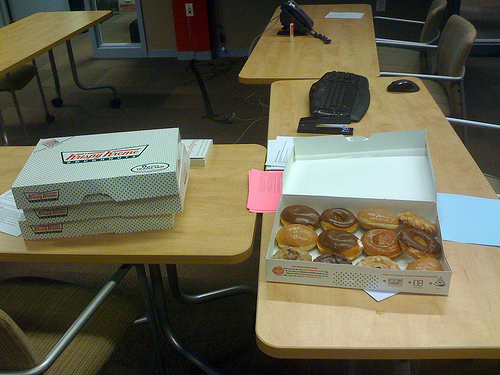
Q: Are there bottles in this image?
A: No, there are no bottles.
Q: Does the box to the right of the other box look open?
A: Yes, the box is open.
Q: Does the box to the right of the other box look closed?
A: No, the box is open.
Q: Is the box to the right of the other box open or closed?
A: The box is open.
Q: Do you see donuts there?
A: Yes, there is a donut.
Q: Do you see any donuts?
A: Yes, there is a donut.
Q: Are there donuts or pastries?
A: Yes, there is a donut.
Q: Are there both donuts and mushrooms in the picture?
A: No, there is a donut but no mushrooms.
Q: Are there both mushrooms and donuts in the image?
A: No, there is a donut but no mushrooms.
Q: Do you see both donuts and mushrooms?
A: No, there is a donut but no mushrooms.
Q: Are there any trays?
A: No, there are no trays.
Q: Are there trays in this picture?
A: No, there are no trays.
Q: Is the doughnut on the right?
A: Yes, the doughnut is on the right of the image.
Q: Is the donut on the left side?
A: No, the donut is on the right of the image.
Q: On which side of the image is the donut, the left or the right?
A: The donut is on the right of the image.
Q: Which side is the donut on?
A: The donut is on the right of the image.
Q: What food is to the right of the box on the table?
A: The food is a donut.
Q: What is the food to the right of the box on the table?
A: The food is a donut.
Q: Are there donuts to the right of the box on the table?
A: Yes, there is a donut to the right of the box.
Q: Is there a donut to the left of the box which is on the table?
A: No, the donut is to the right of the box.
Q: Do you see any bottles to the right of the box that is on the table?
A: No, there is a donut to the right of the box.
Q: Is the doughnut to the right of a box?
A: Yes, the doughnut is to the right of a box.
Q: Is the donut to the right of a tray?
A: No, the donut is to the right of a box.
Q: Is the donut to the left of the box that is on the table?
A: No, the donut is to the right of the box.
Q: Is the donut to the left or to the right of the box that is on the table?
A: The donut is to the right of the box.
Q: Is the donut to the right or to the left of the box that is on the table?
A: The donut is to the right of the box.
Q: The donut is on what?
A: The donut is on the table.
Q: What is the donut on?
A: The donut is on the table.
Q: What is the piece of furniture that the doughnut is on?
A: The piece of furniture is a table.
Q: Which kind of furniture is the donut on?
A: The doughnut is on the table.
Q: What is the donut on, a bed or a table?
A: The donut is on a table.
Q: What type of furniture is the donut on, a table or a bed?
A: The donut is on a table.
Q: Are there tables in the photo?
A: Yes, there is a table.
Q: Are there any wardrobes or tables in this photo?
A: Yes, there is a table.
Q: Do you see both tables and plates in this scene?
A: No, there is a table but no plates.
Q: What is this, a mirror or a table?
A: This is a table.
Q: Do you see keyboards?
A: Yes, there is a keyboard.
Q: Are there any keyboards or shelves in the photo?
A: Yes, there is a keyboard.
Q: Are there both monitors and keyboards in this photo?
A: No, there is a keyboard but no monitors.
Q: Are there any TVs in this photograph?
A: No, there are no tvs.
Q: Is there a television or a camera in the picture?
A: No, there are no televisions or cameras.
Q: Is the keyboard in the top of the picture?
A: Yes, the keyboard is in the top of the image.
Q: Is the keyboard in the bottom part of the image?
A: No, the keyboard is in the top of the image.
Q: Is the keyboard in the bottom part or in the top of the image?
A: The keyboard is in the top of the image.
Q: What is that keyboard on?
A: The keyboard is on the table.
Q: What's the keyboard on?
A: The keyboard is on the table.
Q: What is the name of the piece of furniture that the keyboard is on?
A: The piece of furniture is a table.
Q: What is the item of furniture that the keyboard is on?
A: The piece of furniture is a table.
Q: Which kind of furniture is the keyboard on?
A: The keyboard is on the table.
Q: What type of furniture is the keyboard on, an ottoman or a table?
A: The keyboard is on a table.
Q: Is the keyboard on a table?
A: Yes, the keyboard is on a table.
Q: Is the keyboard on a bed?
A: No, the keyboard is on a table.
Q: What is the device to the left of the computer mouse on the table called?
A: The device is a keyboard.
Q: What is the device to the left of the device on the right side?
A: The device is a keyboard.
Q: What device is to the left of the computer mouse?
A: The device is a keyboard.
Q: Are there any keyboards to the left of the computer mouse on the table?
A: Yes, there is a keyboard to the left of the computer mouse.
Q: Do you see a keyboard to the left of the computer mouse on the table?
A: Yes, there is a keyboard to the left of the computer mouse.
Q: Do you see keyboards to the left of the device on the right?
A: Yes, there is a keyboard to the left of the computer mouse.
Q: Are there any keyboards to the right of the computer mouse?
A: No, the keyboard is to the left of the computer mouse.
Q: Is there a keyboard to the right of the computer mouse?
A: No, the keyboard is to the left of the computer mouse.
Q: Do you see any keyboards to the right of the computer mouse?
A: No, the keyboard is to the left of the computer mouse.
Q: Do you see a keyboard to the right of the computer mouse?
A: No, the keyboard is to the left of the computer mouse.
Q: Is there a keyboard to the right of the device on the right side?
A: No, the keyboard is to the left of the computer mouse.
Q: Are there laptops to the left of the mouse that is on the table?
A: No, there is a keyboard to the left of the mouse.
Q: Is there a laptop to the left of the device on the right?
A: No, there is a keyboard to the left of the mouse.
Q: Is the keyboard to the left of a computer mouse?
A: Yes, the keyboard is to the left of a computer mouse.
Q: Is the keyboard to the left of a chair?
A: No, the keyboard is to the left of a computer mouse.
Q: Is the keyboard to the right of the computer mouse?
A: No, the keyboard is to the left of the computer mouse.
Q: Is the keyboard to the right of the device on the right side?
A: No, the keyboard is to the left of the computer mouse.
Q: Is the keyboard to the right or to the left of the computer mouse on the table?
A: The keyboard is to the left of the mouse.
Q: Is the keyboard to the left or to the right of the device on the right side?
A: The keyboard is to the left of the mouse.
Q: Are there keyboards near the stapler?
A: Yes, there is a keyboard near the stapler.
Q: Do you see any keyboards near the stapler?
A: Yes, there is a keyboard near the stapler.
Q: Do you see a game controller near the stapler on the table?
A: No, there is a keyboard near the stapler.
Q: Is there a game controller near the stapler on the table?
A: No, there is a keyboard near the stapler.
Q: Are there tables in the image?
A: Yes, there is a table.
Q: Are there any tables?
A: Yes, there is a table.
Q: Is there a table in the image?
A: Yes, there is a table.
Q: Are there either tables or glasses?
A: Yes, there is a table.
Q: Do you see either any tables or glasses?
A: Yes, there is a table.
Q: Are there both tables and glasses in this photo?
A: No, there is a table but no glasses.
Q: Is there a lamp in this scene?
A: No, there are no lamps.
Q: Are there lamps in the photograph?
A: No, there are no lamps.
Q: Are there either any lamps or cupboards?
A: No, there are no lamps or cupboards.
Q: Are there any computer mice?
A: Yes, there is a computer mouse.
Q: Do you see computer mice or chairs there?
A: Yes, there is a computer mouse.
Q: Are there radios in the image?
A: No, there are no radios.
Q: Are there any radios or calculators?
A: No, there are no radios or calculators.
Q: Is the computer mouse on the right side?
A: Yes, the computer mouse is on the right of the image.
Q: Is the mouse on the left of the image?
A: No, the mouse is on the right of the image.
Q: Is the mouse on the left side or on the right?
A: The mouse is on the right of the image.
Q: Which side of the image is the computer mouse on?
A: The computer mouse is on the right of the image.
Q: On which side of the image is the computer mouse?
A: The computer mouse is on the right of the image.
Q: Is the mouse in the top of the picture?
A: Yes, the mouse is in the top of the image.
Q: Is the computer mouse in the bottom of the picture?
A: No, the computer mouse is in the top of the image.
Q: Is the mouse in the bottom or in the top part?
A: The mouse is in the top of the image.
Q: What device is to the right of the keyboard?
A: The device is a computer mouse.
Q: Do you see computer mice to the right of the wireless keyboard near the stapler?
A: Yes, there is a computer mouse to the right of the keyboard.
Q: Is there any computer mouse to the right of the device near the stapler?
A: Yes, there is a computer mouse to the right of the keyboard.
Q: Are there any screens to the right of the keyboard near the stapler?
A: No, there is a computer mouse to the right of the keyboard.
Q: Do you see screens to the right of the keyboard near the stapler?
A: No, there is a computer mouse to the right of the keyboard.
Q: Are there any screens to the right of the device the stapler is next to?
A: No, there is a computer mouse to the right of the keyboard.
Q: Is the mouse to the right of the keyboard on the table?
A: Yes, the mouse is to the right of the keyboard.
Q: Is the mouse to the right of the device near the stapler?
A: Yes, the mouse is to the right of the keyboard.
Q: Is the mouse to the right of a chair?
A: No, the mouse is to the right of the keyboard.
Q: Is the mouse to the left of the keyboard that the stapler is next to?
A: No, the mouse is to the right of the keyboard.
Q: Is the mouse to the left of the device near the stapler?
A: No, the mouse is to the right of the keyboard.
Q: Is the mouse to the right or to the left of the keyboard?
A: The mouse is to the right of the keyboard.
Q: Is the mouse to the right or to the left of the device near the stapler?
A: The mouse is to the right of the keyboard.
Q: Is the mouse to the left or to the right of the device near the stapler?
A: The mouse is to the right of the keyboard.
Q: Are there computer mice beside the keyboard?
A: Yes, there is a computer mouse beside the keyboard.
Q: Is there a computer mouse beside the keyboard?
A: Yes, there is a computer mouse beside the keyboard.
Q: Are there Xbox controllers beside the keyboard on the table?
A: No, there is a computer mouse beside the keyboard.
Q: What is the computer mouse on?
A: The computer mouse is on the table.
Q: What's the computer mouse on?
A: The computer mouse is on the table.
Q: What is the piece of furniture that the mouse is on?
A: The piece of furniture is a table.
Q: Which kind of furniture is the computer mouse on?
A: The mouse is on the table.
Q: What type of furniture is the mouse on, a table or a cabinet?
A: The mouse is on a table.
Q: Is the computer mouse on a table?
A: Yes, the computer mouse is on a table.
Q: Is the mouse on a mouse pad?
A: No, the mouse is on a table.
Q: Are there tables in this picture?
A: Yes, there is a table.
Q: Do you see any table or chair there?
A: Yes, there is a table.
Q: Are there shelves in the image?
A: No, there are no shelves.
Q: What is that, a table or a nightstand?
A: That is a table.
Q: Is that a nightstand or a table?
A: That is a table.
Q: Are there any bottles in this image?
A: No, there are no bottles.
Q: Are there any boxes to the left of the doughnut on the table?
A: Yes, there is a box to the left of the donut.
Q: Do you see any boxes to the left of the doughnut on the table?
A: Yes, there is a box to the left of the donut.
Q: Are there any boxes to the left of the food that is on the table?
A: Yes, there is a box to the left of the donut.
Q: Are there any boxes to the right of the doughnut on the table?
A: No, the box is to the left of the doughnut.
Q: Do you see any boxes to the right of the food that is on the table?
A: No, the box is to the left of the doughnut.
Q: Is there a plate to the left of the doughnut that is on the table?
A: No, there is a box to the left of the donut.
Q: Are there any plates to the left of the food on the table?
A: No, there is a box to the left of the donut.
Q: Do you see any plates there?
A: No, there are no plates.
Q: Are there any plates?
A: No, there are no plates.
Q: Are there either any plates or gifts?
A: No, there are no plates or gifts.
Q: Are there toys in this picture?
A: No, there are no toys.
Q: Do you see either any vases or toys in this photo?
A: No, there are no toys or vases.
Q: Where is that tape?
A: The tape is on the floor.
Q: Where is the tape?
A: The tape is on the floor.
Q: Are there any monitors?
A: No, there are no monitors.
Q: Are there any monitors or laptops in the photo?
A: No, there are no monitors or laptops.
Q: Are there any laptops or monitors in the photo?
A: No, there are no monitors or laptops.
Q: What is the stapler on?
A: The stapler is on the table.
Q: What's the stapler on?
A: The stapler is on the table.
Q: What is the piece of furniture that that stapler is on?
A: The piece of furniture is a table.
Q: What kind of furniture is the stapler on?
A: The stapler is on the table.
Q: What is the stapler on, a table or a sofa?
A: The stapler is on a table.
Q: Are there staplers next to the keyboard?
A: Yes, there is a stapler next to the keyboard.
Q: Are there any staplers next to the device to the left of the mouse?
A: Yes, there is a stapler next to the keyboard.